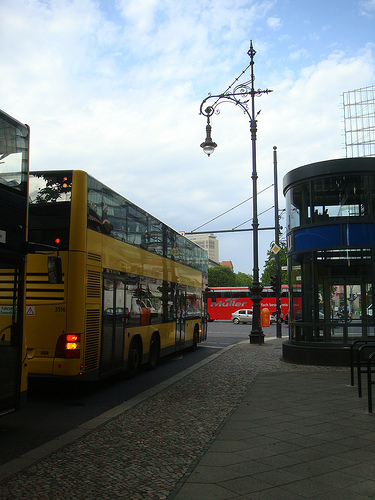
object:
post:
[272, 146, 281, 339]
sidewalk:
[0, 332, 375, 499]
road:
[0, 318, 375, 500]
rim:
[131, 346, 141, 367]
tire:
[129, 342, 142, 373]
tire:
[149, 336, 160, 368]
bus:
[25, 170, 207, 383]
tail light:
[65, 333, 81, 359]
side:
[82, 171, 209, 381]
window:
[87, 175, 163, 259]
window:
[148, 215, 164, 257]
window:
[165, 226, 208, 273]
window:
[125, 281, 176, 328]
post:
[247, 40, 267, 347]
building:
[177, 231, 219, 263]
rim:
[151, 339, 159, 367]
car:
[231, 308, 254, 325]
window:
[239, 310, 246, 314]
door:
[99, 272, 126, 375]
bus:
[207, 285, 303, 323]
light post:
[198, 37, 274, 345]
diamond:
[271, 244, 281, 255]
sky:
[0, 0, 375, 281]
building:
[281, 156, 375, 367]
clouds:
[3, 1, 375, 231]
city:
[0, 0, 374, 498]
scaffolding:
[341, 83, 375, 160]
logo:
[211, 298, 247, 307]